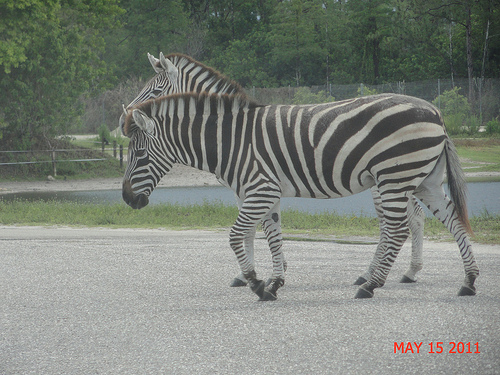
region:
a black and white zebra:
[122, 91, 479, 301]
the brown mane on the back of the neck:
[122, 90, 259, 132]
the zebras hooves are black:
[355, 287, 373, 299]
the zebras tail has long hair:
[441, 117, 475, 238]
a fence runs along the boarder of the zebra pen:
[449, 76, 498, 136]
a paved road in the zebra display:
[1, 231, 498, 373]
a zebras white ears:
[131, 109, 156, 137]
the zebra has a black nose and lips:
[122, 189, 148, 209]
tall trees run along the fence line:
[0, 1, 499, 92]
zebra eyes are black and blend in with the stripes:
[134, 148, 144, 155]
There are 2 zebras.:
[93, 16, 478, 308]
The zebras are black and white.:
[95, 91, 473, 286]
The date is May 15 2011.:
[378, 330, 490, 365]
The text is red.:
[376, 325, 484, 364]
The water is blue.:
[160, 185, 230, 204]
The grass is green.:
[34, 196, 174, 223]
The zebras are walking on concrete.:
[171, 247, 489, 336]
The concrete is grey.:
[42, 253, 185, 343]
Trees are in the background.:
[5, 4, 498, 81]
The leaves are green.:
[8, 17, 73, 154]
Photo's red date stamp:
[391, 340, 481, 355]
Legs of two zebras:
[216, 183, 485, 308]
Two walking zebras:
[106, 60, 495, 300]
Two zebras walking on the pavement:
[112, 13, 482, 305]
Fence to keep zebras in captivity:
[246, 72, 498, 131]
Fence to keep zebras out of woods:
[3, 143, 124, 180]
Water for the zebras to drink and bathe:
[6, 184, 498, 213]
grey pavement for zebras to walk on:
[6, 228, 223, 366]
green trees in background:
[4, 7, 499, 57]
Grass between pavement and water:
[6, 197, 494, 234]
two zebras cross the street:
[116, 48, 478, 298]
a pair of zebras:
[118, 49, 480, 299]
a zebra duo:
[121, 49, 478, 299]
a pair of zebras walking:
[118, 50, 481, 299]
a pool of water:
[1, 170, 499, 220]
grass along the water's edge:
[1, 197, 498, 244]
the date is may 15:
[393, 340, 481, 356]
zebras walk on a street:
[1, 50, 498, 373]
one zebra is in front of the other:
[121, 92, 477, 302]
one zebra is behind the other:
[118, 51, 254, 138]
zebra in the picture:
[120, 100, 484, 320]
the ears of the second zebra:
[144, 34, 205, 78]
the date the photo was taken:
[366, 311, 496, 372]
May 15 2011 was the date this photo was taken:
[384, 337, 485, 357]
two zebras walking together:
[80, 36, 487, 306]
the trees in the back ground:
[0, 13, 140, 185]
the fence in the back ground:
[288, 28, 482, 103]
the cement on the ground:
[39, 251, 181, 362]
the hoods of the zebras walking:
[216, 260, 301, 312]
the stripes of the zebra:
[196, 116, 372, 173]